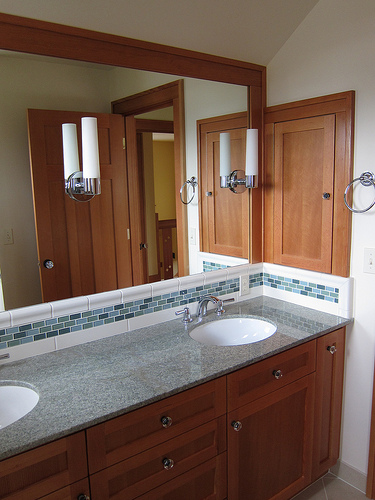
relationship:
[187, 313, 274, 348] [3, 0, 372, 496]
sink in a bathroom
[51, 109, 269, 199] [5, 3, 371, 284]
wall sconces are on a mirror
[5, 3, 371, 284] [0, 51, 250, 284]
mirror on mirror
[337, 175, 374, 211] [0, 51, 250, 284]
towel ring on mirror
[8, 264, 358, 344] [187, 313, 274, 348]
tile above sink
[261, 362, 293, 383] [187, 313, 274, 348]
knob under sink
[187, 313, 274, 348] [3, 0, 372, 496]
sink are in bathroom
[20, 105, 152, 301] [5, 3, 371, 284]
door in mirror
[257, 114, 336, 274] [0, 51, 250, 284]
towel cabinet on mirror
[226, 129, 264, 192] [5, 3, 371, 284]
light on mirror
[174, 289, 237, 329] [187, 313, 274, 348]
faucet next to sink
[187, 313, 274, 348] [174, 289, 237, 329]
sink next to faucet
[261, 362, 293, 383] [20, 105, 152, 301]
knob on door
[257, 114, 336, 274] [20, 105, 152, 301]
cabinet has door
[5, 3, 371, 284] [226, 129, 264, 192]
mirror has light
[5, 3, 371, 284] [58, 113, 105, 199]
mirror has light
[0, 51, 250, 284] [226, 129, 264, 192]
mirror has light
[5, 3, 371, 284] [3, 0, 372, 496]
mirror in bathroom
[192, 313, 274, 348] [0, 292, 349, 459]
sink on counter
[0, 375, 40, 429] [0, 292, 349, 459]
sink on counter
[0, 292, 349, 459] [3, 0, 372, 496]
counter in bathroom